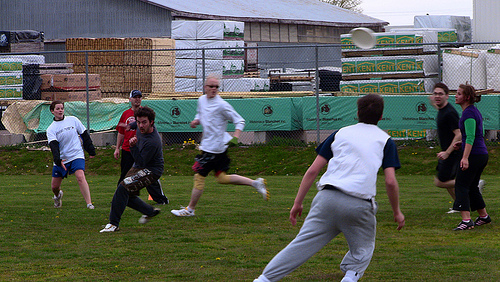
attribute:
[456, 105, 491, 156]
shirt — green, purple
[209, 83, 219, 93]
sunglasses — dark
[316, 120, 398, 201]
shirt — blue, white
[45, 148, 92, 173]
shirt —  royal blue,  Man's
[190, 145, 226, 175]
black shorts — black  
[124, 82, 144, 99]
hat — baseball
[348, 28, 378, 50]
frisbee — white, flying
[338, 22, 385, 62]
frisbee — white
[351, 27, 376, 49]
frisbee — white, in the air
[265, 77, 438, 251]
man — running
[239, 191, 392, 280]
sweat pants — gray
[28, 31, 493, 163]
fence — metal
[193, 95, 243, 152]
shirt — white, long sleeve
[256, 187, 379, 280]
sweatpants — gray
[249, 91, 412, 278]
man — wearing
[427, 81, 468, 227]
man — black-dressed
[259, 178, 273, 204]
bottom — yellow